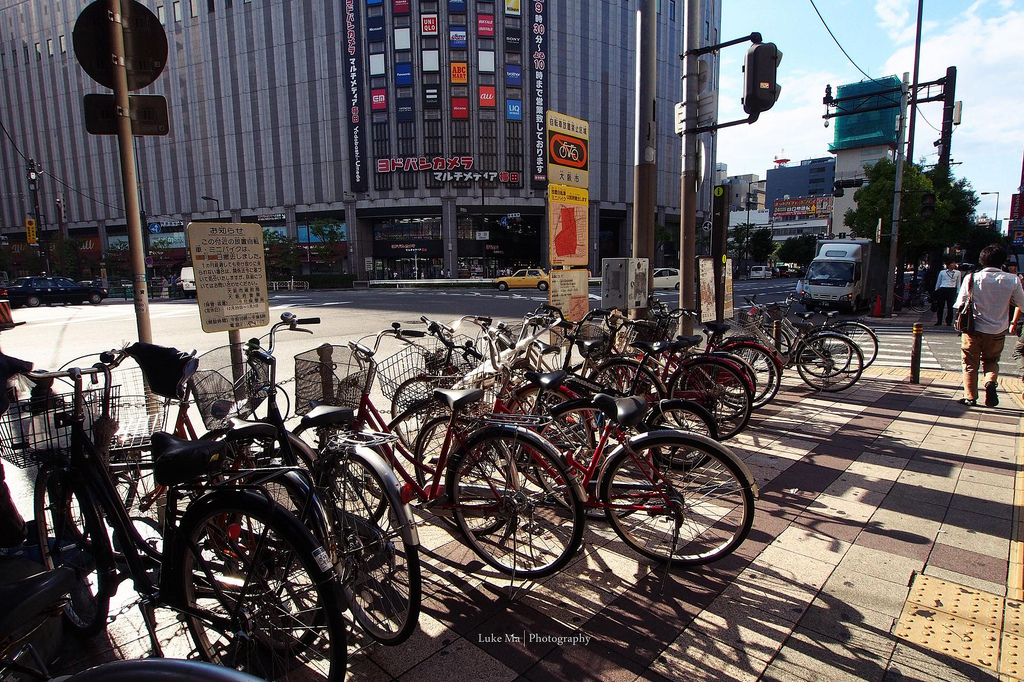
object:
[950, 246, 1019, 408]
person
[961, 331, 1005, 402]
pants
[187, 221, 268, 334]
sign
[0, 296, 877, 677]
bikes